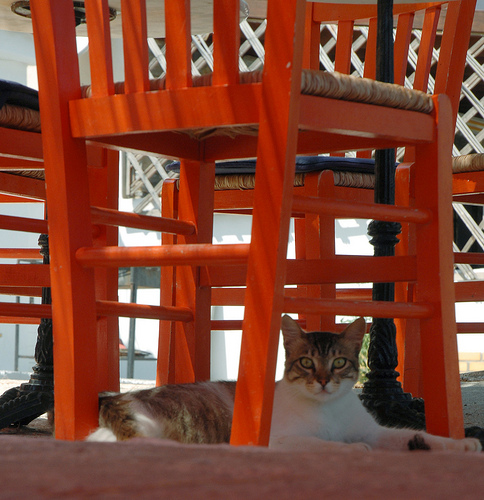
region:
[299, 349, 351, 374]
green eyes on a cat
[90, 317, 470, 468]
a cat under a chair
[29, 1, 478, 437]
an orange chair at a table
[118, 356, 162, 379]
water visible through chair legs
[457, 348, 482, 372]
a brick wall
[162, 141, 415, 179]
a blue cushion in a chair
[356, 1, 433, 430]
a support post on a table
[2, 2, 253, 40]
the underside of a table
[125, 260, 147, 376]
a metal post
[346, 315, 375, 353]
a cat ear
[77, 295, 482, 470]
The cat is laying down.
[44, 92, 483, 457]
One cat under the chair.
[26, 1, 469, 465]
The chair is orange.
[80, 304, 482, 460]
The cat is brown and white.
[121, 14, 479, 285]
White fence in background.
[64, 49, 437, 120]
The seat is brown.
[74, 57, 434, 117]
The seat is wicker.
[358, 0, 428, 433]
The pole is black.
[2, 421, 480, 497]
The ground is beige.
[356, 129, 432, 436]
The pole is metal.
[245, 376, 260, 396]
the chair is wooden red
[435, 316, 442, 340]
the chair is wooden red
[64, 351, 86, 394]
the chair is wooden red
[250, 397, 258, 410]
the chair is wooden red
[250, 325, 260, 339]
the chair is wooden red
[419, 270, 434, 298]
the chair is wooden red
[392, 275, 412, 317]
the chair is wooden red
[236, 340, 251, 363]
the chair is wooden red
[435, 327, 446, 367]
the chair is wooden red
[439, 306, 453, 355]
the chair is wooden red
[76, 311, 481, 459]
cat resting on the floor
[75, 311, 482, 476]
white and brown cat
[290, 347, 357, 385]
yellow cat eyes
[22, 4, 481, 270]
red wooden chair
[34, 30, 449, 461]
cat underneath a red wood chair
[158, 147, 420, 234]
blue chair cushion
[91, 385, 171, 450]
brown and black cat's tail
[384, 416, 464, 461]
brown spot on cats leg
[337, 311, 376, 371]
pointy cat ear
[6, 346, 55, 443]
iron table stand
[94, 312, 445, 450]
Brown and white cat with green eyes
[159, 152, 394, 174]
Dark blue seat cushion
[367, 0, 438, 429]
Black table support pedestal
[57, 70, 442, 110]
Woven reed chair seat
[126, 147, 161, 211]
White trellis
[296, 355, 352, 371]
Cat's alert green eyes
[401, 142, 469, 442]
Leg of orange patio chair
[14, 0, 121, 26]
Top of support pedestal meeting bottom of tabletop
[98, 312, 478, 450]
Kitty cat relaxing under the table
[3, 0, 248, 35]
Round table top